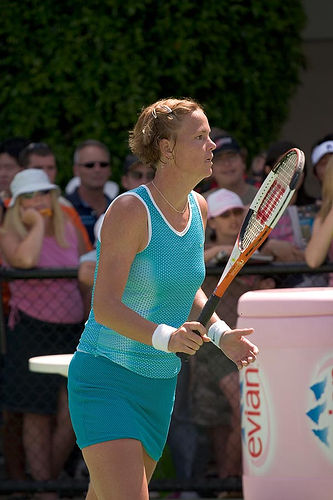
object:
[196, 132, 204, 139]
eye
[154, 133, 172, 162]
ear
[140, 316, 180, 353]
wrist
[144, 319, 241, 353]
sweat band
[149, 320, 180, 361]
wrist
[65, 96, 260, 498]
lindsay davenport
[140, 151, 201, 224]
necklace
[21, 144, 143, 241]
crowd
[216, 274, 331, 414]
cooler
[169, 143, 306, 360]
tennis racquet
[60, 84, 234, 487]
woman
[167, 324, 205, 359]
hand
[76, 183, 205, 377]
shirt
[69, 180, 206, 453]
blue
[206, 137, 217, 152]
nose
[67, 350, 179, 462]
skirt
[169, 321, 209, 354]
hand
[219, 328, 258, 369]
hand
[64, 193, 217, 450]
outfit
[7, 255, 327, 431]
fence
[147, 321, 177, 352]
band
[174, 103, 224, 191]
face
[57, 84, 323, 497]
tennis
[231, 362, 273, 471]
logo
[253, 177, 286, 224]
letter